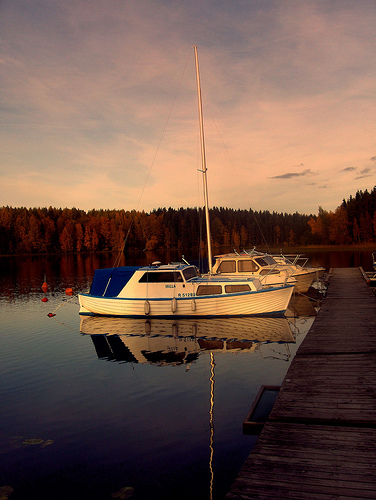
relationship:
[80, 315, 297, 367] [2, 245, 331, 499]
reflection in water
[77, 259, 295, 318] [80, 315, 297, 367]
boat in reflection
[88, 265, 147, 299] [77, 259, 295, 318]
tarp on boat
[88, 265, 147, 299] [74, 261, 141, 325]
tarp on end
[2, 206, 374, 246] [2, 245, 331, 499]
foliage along water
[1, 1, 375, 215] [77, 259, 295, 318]
sky above boat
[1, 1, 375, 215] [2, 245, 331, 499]
sky above water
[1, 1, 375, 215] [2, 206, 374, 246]
sky above foliage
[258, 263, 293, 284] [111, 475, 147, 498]
equipment for fishing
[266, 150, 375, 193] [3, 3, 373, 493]
clouds approaching area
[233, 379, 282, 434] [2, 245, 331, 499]
debris in lake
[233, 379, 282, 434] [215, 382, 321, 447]
debris on bottom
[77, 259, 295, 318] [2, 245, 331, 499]
boat in water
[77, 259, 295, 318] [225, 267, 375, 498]
boat at dock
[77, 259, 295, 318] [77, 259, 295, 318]
boat behind boat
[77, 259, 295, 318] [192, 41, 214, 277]
boat has mast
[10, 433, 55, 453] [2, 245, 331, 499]
pads in water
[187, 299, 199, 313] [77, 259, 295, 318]
float on boat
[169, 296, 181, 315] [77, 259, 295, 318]
float on boat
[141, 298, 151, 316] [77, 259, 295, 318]
float on boat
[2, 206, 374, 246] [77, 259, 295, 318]
foliage behind boat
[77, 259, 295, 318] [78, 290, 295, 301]
boat has blue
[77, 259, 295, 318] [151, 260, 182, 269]
boat has accessory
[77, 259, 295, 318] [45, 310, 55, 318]
boat has buoy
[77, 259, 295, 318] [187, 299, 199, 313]
boat has float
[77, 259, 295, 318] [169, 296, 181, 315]
boat has float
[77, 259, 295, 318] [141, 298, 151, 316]
boat has float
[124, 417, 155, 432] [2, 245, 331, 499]
fish in water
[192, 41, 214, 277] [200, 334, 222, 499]
mast has reflection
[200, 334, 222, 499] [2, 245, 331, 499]
reflection in water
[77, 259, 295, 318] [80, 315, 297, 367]
boat has reflection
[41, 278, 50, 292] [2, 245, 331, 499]
buoy in water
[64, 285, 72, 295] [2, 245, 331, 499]
buoy in water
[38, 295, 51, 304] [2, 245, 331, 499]
buoy in water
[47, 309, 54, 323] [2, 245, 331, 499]
buoy in water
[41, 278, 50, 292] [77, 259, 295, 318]
buoy behind boat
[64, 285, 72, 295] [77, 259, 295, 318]
buoy behind boat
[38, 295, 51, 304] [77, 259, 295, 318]
buoy behind boat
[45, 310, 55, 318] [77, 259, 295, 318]
buoy behind boat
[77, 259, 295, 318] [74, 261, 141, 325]
boat has end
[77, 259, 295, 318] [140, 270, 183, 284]
boat has window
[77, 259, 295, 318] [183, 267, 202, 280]
boat has window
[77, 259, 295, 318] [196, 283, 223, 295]
boat has window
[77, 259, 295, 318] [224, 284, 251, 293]
boat has window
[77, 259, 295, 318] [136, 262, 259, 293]
boat has cabin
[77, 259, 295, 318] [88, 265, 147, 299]
boat has tarp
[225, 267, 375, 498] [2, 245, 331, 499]
dock on water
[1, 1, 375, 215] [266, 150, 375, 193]
sky has clouds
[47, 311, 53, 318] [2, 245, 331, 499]
buoy in water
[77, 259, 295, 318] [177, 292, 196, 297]
boat has number